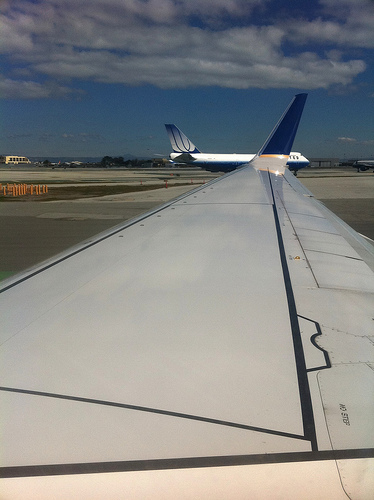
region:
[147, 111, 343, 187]
This is a plane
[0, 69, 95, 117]
Section of a sky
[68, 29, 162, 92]
Section of a sky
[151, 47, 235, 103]
Section of a sky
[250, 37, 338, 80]
Section of a sky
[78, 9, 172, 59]
Section of a sky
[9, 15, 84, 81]
Section of a sky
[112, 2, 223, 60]
Section of a sky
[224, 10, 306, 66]
Section of a sky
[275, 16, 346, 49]
Section of a sky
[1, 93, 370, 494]
the entire wing of an airplane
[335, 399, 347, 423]
writing on the wing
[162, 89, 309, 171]
an airplane heading to the right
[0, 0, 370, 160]
the sky over the airport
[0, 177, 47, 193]
a group of orange cones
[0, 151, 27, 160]
a light colored bus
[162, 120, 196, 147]
blue and white tail of a plane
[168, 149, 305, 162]
white body of the plane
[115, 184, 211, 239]
row of rivets on left side of the wing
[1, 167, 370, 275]
the tarmac the planes are on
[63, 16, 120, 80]
this is a cloud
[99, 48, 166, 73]
this is a cloud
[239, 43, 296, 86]
this is a cloud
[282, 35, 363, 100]
this is a cloud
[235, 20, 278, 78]
this is a cloud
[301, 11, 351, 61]
this is a cloud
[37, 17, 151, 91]
this is a cloud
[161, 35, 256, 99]
this is a cloud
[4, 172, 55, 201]
Big orange poles in ground by plane.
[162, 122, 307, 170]
airplane on the run way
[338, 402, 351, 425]
words on the wing of a plane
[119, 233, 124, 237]
bolt on the plane's wing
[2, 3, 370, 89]
fluffy clouds in the sky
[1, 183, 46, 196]
group of warning cones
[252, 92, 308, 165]
wing tip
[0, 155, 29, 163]
tan building behind the runway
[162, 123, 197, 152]
white logo and the plane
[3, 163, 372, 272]
concrete run way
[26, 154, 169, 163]
mountains in the distance